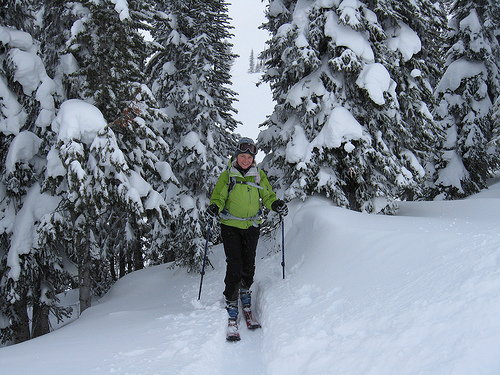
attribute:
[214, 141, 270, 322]
skier — smiling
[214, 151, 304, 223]
jacket — green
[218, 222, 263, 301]
pants — black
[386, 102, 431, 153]
pine needles — snow topped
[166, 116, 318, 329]
skier — smiling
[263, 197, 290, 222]
gloves — thick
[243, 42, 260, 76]
tree — evergreen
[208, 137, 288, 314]
person — athletic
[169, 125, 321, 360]
skiier —  Woman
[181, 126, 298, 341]
hair — dark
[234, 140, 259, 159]
ski goggles — black, grey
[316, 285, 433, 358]
snow — deep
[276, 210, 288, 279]
ski pole — black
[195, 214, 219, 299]
ski pole — black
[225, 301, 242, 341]
ski — black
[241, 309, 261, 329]
ski — black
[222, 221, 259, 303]
pants — black, winter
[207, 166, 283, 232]
coat — green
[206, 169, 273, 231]
jacket — green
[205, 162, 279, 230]
ski jacket — yellow, white